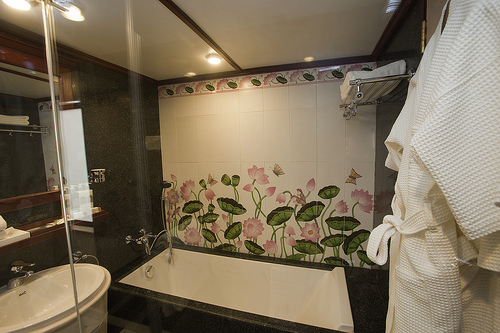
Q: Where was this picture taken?
A: Bathroom.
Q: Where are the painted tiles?
A: Above the bathtub.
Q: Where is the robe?
A: Hanging on the wall.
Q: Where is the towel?
A: On the towel rack.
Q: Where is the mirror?
A: Above the sink.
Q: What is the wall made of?
A: Granite.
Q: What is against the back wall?
A: A bathtub.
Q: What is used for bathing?
A: A bathtub.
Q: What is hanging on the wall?
A: A robe.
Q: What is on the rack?
A: A towel.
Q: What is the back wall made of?
A: Tile.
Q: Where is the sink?
A: By the tub.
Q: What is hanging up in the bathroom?
A: A robe.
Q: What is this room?
A: A bathroom.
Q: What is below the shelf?
A: A sink.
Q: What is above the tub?
A: A shelf.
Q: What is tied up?
A: A belt of a robe.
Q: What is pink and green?
A: Flowers.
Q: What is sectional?
A: The ceiling.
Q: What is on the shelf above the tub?
A: A towel.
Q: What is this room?
A: A bathroom.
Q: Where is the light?
A: On the ceilings.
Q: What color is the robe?
A: White.